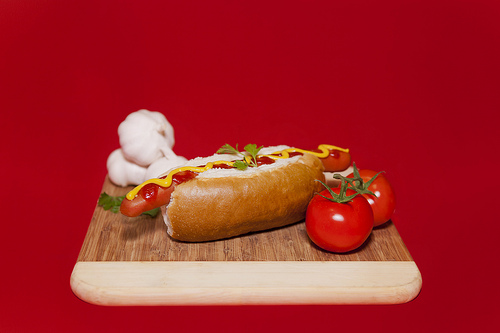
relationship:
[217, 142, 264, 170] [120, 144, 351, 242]
parsely on top of hot dog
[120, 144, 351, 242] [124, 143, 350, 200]
hot dog has mustard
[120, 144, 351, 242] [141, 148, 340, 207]
hot dog has ketchup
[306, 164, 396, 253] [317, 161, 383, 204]
tomatoes have stems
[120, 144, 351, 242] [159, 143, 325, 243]
hot dog has bun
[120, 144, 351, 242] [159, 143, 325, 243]
hot dog larger than bun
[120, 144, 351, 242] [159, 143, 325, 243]
hot dog on bun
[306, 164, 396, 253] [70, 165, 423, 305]
tomatoes on cutting board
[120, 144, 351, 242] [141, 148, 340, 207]
hot dog with ketchup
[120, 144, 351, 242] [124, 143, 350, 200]
hot dog with mustard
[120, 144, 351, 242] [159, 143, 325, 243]
hot dog in between bun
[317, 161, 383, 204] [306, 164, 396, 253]
stems on tomatoes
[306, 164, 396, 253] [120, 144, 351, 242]
tomatoes next to hot dog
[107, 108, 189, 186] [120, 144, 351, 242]
garlic behind hot dog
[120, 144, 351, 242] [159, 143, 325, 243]
hot dog in bun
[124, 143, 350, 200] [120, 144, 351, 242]
mustard on hot dog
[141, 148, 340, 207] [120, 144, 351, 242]
ketchup on hot dog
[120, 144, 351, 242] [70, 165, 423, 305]
hot dog on cutting board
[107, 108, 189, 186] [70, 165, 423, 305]
garlic on cutting board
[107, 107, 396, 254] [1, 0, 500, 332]
food in front of background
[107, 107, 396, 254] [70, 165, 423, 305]
food on cutting board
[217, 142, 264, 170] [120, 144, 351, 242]
parsely on hot dog